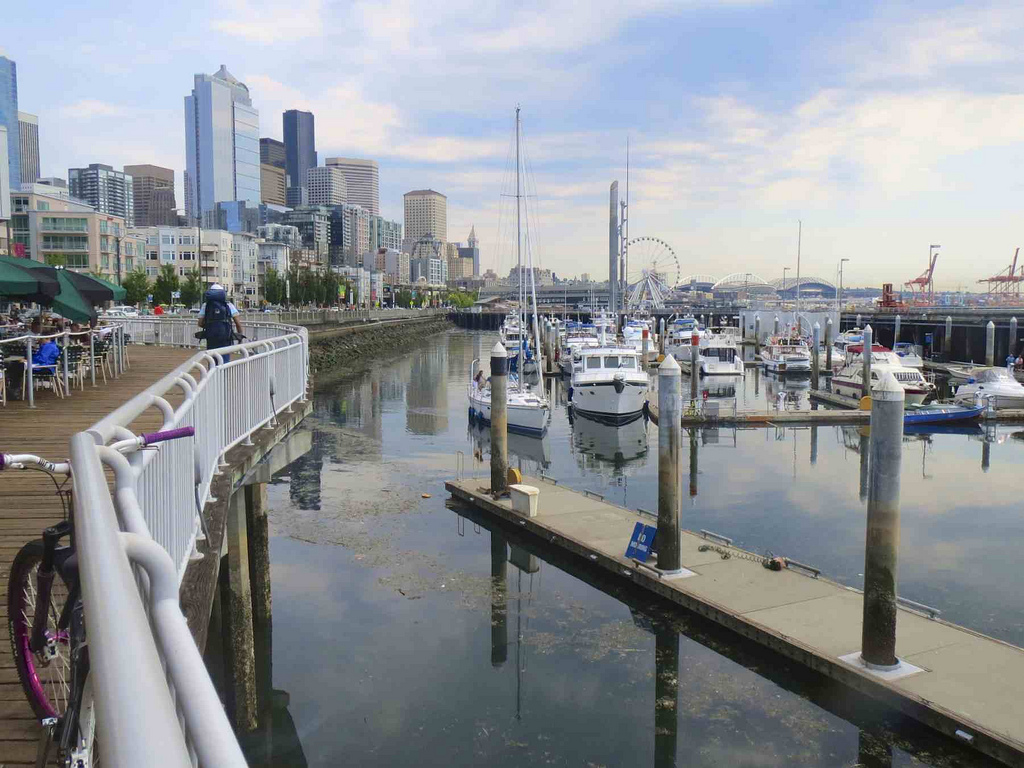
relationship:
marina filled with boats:
[471, 284, 994, 753] [423, 279, 1019, 422]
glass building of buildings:
[180, 61, 263, 235] [0, 55, 501, 290]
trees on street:
[252, 257, 364, 311] [230, 268, 442, 331]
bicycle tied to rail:
[28, 425, 98, 730] [64, 299, 343, 762]